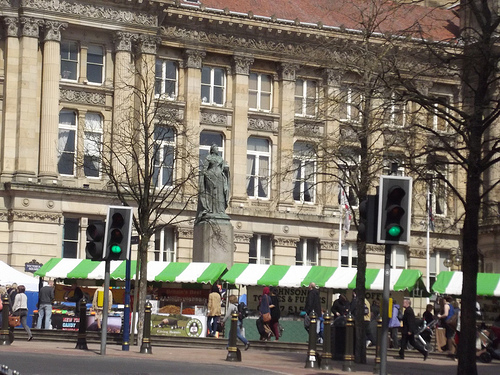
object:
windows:
[259, 77, 272, 94]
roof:
[218, 263, 420, 292]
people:
[255, 284, 272, 341]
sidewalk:
[0, 327, 500, 374]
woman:
[7, 284, 34, 344]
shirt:
[12, 290, 32, 310]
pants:
[10, 308, 32, 340]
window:
[57, 108, 79, 129]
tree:
[346, 0, 500, 374]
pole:
[225, 282, 230, 335]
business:
[220, 263, 430, 344]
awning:
[33, 257, 228, 285]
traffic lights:
[375, 177, 413, 246]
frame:
[375, 176, 413, 246]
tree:
[246, 2, 449, 363]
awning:
[0, 256, 41, 292]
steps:
[0, 336, 455, 362]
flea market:
[0, 256, 500, 359]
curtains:
[243, 134, 256, 191]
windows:
[245, 135, 271, 152]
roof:
[157, 6, 466, 57]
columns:
[41, 27, 60, 182]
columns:
[111, 38, 133, 181]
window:
[80, 154, 99, 177]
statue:
[196, 146, 232, 224]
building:
[0, 0, 500, 315]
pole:
[224, 307, 239, 362]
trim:
[230, 310, 240, 320]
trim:
[223, 348, 242, 361]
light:
[386, 224, 405, 237]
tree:
[80, 42, 228, 351]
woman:
[221, 294, 252, 351]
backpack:
[237, 301, 248, 322]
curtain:
[83, 111, 102, 173]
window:
[80, 112, 106, 133]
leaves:
[321, 44, 331, 54]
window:
[59, 58, 78, 79]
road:
[0, 330, 500, 373]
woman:
[385, 297, 400, 347]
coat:
[386, 305, 400, 328]